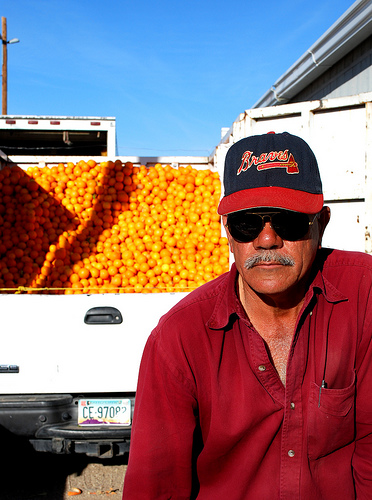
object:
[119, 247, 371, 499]
red shirt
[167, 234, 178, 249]
oranges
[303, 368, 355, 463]
pocket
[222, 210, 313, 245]
sunglasses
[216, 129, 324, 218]
baseball hat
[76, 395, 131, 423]
license plate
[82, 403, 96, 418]
ce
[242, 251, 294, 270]
mustache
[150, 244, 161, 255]
fruit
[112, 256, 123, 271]
fruits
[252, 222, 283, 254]
nose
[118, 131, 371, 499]
man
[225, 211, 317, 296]
man's face